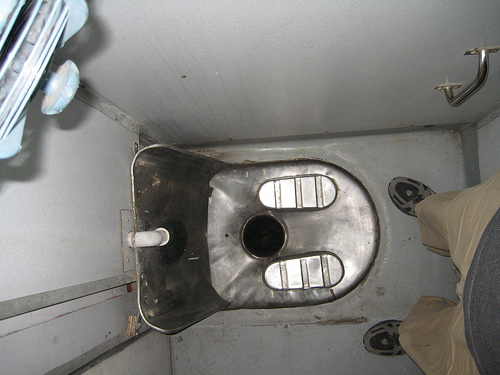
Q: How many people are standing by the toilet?
A: One.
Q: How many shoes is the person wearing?
A: Two.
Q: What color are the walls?
A: White.